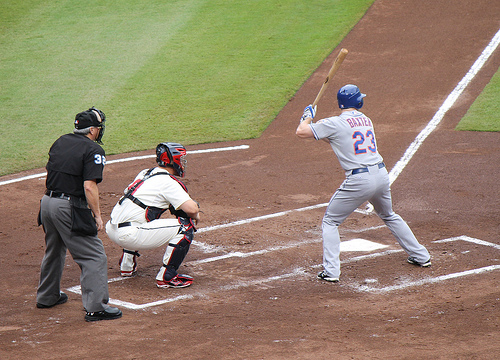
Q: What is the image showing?
A: It is showing a field.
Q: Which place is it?
A: It is a field.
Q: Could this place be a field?
A: Yes, it is a field.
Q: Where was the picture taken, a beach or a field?
A: It was taken at a field.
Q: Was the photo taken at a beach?
A: No, the picture was taken in a field.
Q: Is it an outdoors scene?
A: Yes, it is outdoors.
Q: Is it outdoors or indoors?
A: It is outdoors.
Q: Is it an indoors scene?
A: No, it is outdoors.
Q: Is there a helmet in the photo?
A: Yes, there is a helmet.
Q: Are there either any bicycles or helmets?
A: Yes, there is a helmet.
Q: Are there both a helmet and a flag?
A: No, there is a helmet but no flags.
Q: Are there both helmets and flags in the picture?
A: No, there is a helmet but no flags.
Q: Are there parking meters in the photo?
A: No, there are no parking meters.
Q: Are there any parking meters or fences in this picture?
A: No, there are no parking meters or fences.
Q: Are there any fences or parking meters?
A: No, there are no parking meters or fences.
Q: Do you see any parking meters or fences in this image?
A: No, there are no parking meters or fences.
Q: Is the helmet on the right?
A: Yes, the helmet is on the right of the image.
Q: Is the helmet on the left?
A: No, the helmet is on the right of the image.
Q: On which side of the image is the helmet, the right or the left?
A: The helmet is on the right of the image.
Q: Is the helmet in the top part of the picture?
A: Yes, the helmet is in the top of the image.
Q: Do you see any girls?
A: No, there are no girls.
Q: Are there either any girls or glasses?
A: No, there are no girls or glasses.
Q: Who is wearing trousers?
A: The man is wearing trousers.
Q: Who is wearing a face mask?
A: The man is wearing a face mask.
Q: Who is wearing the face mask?
A: The man is wearing a face mask.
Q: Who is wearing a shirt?
A: The man is wearing a shirt.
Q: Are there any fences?
A: No, there are no fences.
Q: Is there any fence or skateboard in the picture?
A: No, there are no fences or skateboards.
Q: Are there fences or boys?
A: No, there are no fences or boys.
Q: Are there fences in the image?
A: No, there are no fences.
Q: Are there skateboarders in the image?
A: No, there are no skateboarders.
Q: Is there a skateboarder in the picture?
A: No, there are no skateboarders.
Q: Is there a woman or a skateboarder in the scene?
A: No, there are no skateboarders or women.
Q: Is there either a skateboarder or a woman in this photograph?
A: No, there are no skateboarders or women.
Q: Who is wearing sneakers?
A: The man is wearing sneakers.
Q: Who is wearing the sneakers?
A: The man is wearing sneakers.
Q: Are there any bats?
A: Yes, there is a bat.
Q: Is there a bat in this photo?
A: Yes, there is a bat.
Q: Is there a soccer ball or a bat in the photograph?
A: Yes, there is a bat.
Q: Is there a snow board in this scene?
A: No, there are no snowboards.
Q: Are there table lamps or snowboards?
A: No, there are no snowboards or table lamps.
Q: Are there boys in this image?
A: No, there are no boys.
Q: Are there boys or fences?
A: No, there are no boys or fences.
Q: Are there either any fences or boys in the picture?
A: No, there are no boys or fences.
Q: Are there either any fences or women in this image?
A: No, there are no fences or women.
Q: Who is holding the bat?
A: The man is holding the bat.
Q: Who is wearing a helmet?
A: The man is wearing a helmet.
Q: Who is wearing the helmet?
A: The man is wearing a helmet.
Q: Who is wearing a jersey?
A: The man is wearing a jersey.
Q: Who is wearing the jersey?
A: The man is wearing a jersey.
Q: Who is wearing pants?
A: The man is wearing pants.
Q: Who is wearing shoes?
A: The man is wearing shoes.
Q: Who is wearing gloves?
A: The man is wearing gloves.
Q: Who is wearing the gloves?
A: The man is wearing gloves.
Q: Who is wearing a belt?
A: The man is wearing a belt.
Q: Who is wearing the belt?
A: The man is wearing a belt.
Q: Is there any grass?
A: Yes, there is grass.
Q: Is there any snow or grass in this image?
A: Yes, there is grass.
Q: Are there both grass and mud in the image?
A: No, there is grass but no mud.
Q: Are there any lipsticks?
A: No, there are no lipsticks.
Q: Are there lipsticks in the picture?
A: No, there are no lipsticks.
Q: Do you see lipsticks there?
A: No, there are no lipsticks.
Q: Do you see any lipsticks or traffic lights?
A: No, there are no lipsticks or traffic lights.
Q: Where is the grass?
A: The grass is on the field.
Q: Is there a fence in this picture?
A: No, there are no fences.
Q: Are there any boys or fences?
A: No, there are no fences or boys.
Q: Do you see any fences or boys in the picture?
A: No, there are no fences or boys.